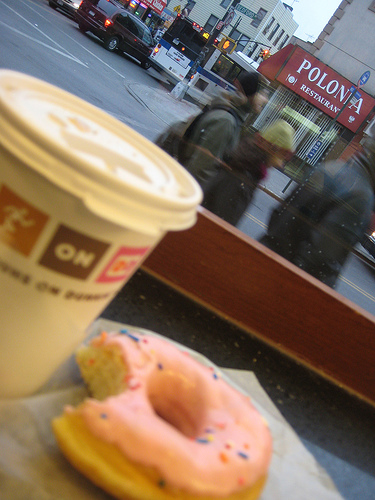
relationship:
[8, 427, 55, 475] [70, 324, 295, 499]
paper under donut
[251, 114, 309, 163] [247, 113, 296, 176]
cap on head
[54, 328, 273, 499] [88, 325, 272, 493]
donut with icing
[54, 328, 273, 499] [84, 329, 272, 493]
donut with pink icing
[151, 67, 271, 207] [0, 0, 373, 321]
person walking past window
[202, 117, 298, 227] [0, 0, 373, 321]
person walking past window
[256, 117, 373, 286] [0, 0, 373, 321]
person walking past window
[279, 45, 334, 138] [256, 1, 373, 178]
sign on store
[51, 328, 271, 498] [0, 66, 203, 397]
coffee beside donut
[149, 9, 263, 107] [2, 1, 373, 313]
bus on street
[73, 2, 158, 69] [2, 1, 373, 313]
minivan on street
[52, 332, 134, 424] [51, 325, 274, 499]
bite taken from donut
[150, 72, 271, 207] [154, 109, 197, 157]
person with backpack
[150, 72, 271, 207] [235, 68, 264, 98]
person wearing cap